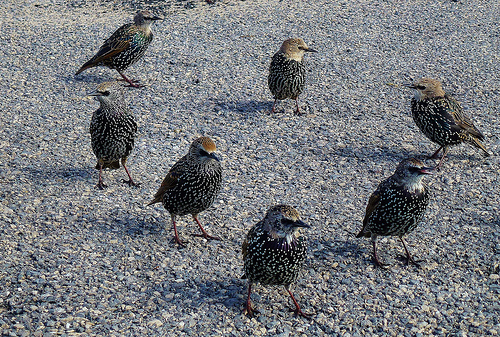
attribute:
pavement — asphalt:
[84, 102, 289, 217]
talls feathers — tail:
[159, 164, 224, 211]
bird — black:
[246, 21, 319, 120]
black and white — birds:
[259, 195, 433, 270]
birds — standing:
[164, 144, 302, 259]